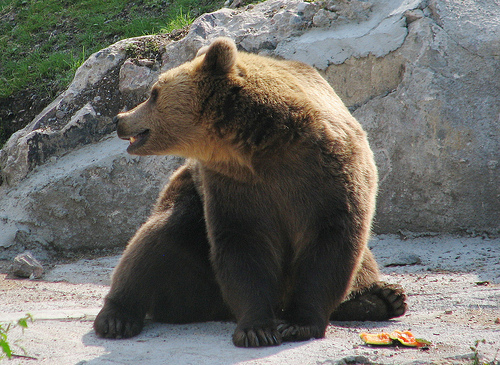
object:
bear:
[93, 36, 414, 349]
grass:
[5, 1, 263, 137]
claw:
[233, 319, 283, 348]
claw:
[93, 307, 143, 338]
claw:
[276, 314, 324, 341]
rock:
[0, 0, 499, 281]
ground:
[10, 240, 499, 364]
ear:
[148, 88, 158, 102]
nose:
[112, 116, 119, 125]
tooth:
[129, 136, 135, 143]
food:
[359, 329, 431, 347]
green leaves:
[0, 310, 38, 364]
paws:
[95, 285, 405, 349]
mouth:
[115, 128, 152, 152]